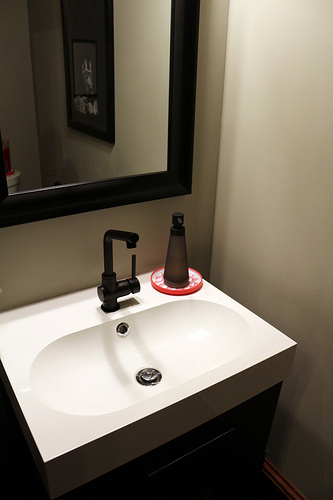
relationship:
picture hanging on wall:
[59, 1, 120, 145] [1, 2, 332, 499]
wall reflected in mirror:
[1, 2, 332, 499] [2, 2, 204, 224]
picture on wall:
[60, 1, 116, 144] [207, 0, 332, 499]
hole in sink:
[118, 357, 185, 402] [3, 269, 296, 494]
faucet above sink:
[96, 227, 141, 314] [29, 299, 251, 424]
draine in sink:
[134, 366, 162, 387] [3, 269, 296, 494]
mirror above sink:
[2, 10, 255, 229] [11, 277, 330, 425]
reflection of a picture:
[66, 31, 128, 127] [60, 1, 116, 144]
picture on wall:
[60, 1, 116, 144] [239, 55, 306, 163]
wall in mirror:
[239, 55, 306, 163] [4, 138, 171, 196]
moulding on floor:
[262, 452, 309, 499] [118, 454, 312, 498]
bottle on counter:
[162, 211, 189, 287] [1, 271, 297, 465]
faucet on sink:
[94, 226, 173, 294] [1, 281, 301, 419]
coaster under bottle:
[149, 266, 202, 295] [162, 211, 189, 287]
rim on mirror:
[98, 161, 217, 203] [2, 2, 204, 224]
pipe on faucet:
[96, 238, 132, 318] [87, 224, 155, 312]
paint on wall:
[16, 236, 95, 286] [1, 2, 332, 499]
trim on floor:
[261, 456, 308, 498] [239, 473, 285, 497]